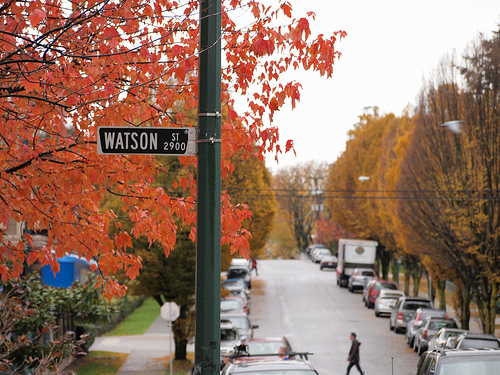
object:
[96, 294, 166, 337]
grass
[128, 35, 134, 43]
leaves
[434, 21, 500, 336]
trees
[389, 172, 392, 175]
leaves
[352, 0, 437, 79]
clouds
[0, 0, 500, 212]
sky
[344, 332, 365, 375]
man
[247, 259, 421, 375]
street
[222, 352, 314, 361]
rack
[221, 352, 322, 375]
car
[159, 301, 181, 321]
back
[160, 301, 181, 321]
stop sign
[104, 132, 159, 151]
watson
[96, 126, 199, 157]
sign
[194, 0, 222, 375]
pole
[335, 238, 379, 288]
box truck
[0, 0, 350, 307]
tree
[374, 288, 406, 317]
cars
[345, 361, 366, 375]
pants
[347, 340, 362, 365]
jacket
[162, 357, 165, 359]
dead leaves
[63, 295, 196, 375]
ground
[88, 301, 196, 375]
sidewalk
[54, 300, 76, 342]
fencing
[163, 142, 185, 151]
2900 block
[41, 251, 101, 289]
object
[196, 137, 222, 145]
clamp